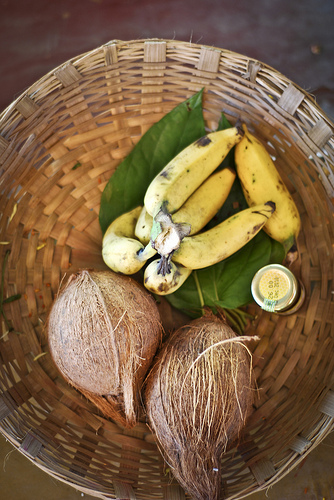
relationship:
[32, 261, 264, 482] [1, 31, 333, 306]
coconuts in a basket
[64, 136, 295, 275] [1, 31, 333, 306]
bananas in a basket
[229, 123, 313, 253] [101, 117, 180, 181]
banana on a green leaf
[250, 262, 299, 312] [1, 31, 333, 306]
cap in a basket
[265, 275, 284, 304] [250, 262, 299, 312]
26 of dec on a cap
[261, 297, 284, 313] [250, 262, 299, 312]
sticker on a cap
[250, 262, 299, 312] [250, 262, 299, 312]
cap on cap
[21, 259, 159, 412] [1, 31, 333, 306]
coconut in a basket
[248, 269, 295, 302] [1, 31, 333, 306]
cap in a basket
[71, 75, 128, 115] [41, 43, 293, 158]
side of a wicker basket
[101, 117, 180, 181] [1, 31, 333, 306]
green leaf in a basket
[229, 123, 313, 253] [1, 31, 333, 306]
banana in a basket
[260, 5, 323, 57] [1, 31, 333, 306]
orange flecks in a basket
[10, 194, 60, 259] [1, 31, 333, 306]
yellow flecks in a basket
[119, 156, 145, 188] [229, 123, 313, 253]
leaf stem of a banana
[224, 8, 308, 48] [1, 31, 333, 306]
table under a basket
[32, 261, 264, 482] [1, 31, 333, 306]
coconuts in basket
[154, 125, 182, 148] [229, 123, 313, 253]
leaves below banana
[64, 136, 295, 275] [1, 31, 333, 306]
bananas in basket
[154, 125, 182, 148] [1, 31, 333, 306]
leaves in basket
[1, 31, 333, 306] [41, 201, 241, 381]
basket filled with fruit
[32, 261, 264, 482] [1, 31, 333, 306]
hairy coconuts in basket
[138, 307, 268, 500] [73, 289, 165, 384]
hairy coconut shaped hairy coconut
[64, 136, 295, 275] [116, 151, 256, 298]
bananas on green leaves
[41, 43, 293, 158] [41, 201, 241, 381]
wicker basket with fruit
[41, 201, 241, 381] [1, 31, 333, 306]
bananas and coconuts in a basket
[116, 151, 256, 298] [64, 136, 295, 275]
green leaves under bananas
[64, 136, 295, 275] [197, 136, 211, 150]
bananas with brown spot